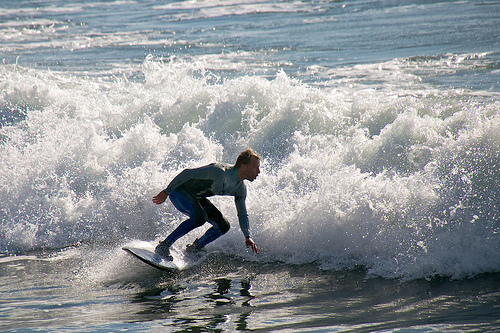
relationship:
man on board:
[152, 149, 262, 263] [120, 245, 210, 274]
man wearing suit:
[152, 149, 262, 263] [163, 161, 251, 255]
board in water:
[120, 245, 210, 274] [0, 1, 500, 332]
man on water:
[152, 149, 262, 263] [0, 1, 500, 332]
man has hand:
[152, 149, 262, 263] [245, 235, 260, 256]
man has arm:
[152, 149, 262, 263] [163, 165, 225, 197]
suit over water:
[163, 161, 251, 255] [0, 1, 500, 332]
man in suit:
[152, 149, 262, 263] [163, 161, 251, 255]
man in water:
[152, 149, 262, 263] [0, 1, 500, 332]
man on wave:
[152, 149, 262, 263] [1, 57, 500, 293]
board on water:
[120, 245, 210, 274] [0, 1, 500, 332]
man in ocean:
[152, 149, 262, 263] [0, 0, 500, 332]